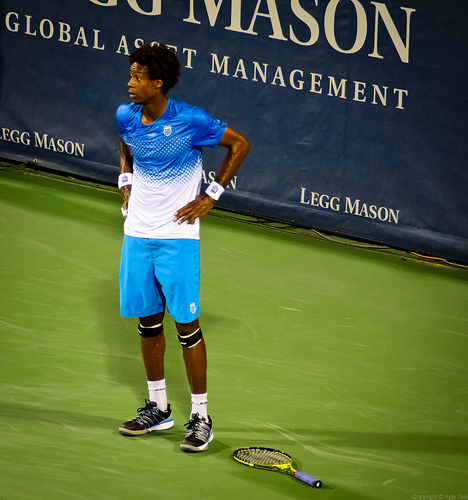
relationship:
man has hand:
[115, 43, 251, 453] [175, 194, 215, 225]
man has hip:
[115, 43, 251, 453] [169, 202, 207, 244]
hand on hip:
[175, 194, 215, 225] [169, 202, 207, 244]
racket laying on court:
[233, 447, 321, 489] [1, 97, 465, 498]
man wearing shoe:
[115, 43, 251, 453] [180, 413, 214, 453]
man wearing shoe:
[115, 43, 251, 453] [120, 400, 175, 436]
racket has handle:
[233, 447, 321, 489] [292, 469, 323, 489]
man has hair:
[115, 43, 251, 453] [127, 43, 182, 95]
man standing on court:
[115, 43, 251, 453] [1, 97, 465, 498]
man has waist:
[115, 43, 251, 453] [128, 180, 201, 225]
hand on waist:
[175, 194, 215, 225] [128, 180, 201, 225]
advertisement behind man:
[2, 0, 467, 270] [115, 43, 251, 453]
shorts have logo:
[120, 234, 203, 324] [189, 302, 198, 315]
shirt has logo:
[115, 101, 228, 241] [162, 124, 173, 137]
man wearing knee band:
[115, 43, 251, 453] [137, 324, 165, 338]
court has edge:
[1, 97, 465, 498] [1, 159, 467, 272]